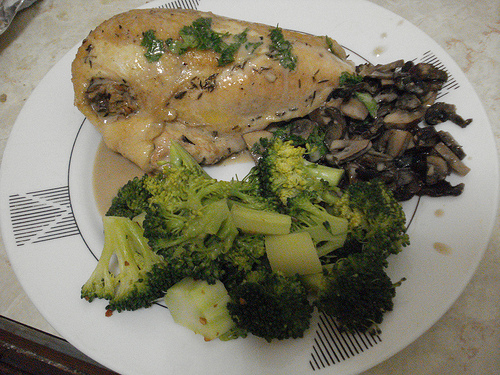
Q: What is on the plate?
A: Food.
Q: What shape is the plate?
A: Round.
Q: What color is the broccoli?
A: Green.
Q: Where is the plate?
A: On the table.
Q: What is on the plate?
A: Food.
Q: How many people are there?
A: None.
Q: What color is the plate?
A: White.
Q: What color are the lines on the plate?
A: Black.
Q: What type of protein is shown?
A: Chicken.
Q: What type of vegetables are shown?
A: Broccoli.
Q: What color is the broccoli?
A: Green.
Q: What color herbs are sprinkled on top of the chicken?
A: Green.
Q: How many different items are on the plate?
A: 3.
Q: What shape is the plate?
A: Round.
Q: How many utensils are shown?
A: None.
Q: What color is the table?
A: Tan and brown.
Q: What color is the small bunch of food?
A: Brown.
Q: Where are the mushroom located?
A: Right side.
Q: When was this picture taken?
A: Dinner time.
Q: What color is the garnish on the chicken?
A: Green.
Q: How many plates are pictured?
A: One.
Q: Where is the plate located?
A: Counter.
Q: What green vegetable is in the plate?
A: Broccoli.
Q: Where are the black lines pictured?
A: On plate.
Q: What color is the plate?
A: White.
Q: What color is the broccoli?
A: Green.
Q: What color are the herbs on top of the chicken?
A: Green.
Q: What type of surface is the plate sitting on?
A: Marble.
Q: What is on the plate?
A: Chicken and vegetables is on the plate.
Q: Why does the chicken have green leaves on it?
A: It is for seasoning the chicken.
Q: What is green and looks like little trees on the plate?
A: The broccoli looks like little trees.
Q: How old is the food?
A: It is not old at all it is fresh.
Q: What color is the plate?
A: The plate is white and black.